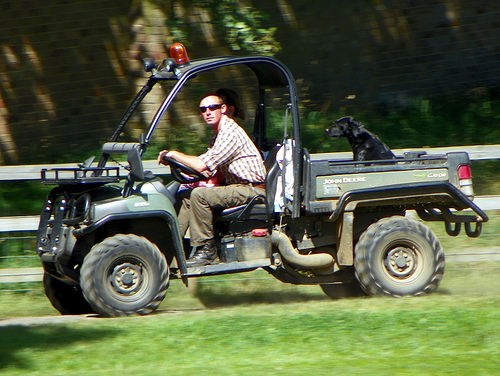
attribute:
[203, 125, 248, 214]
shirt — red, plaid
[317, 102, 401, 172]
dog — black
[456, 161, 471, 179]
head light — red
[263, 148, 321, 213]
jacket — white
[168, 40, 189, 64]
light — red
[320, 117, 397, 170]
dog — black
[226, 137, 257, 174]
shirt — on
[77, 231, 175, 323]
tire — black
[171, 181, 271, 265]
pants — on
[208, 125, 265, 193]
shirt — long sleeved